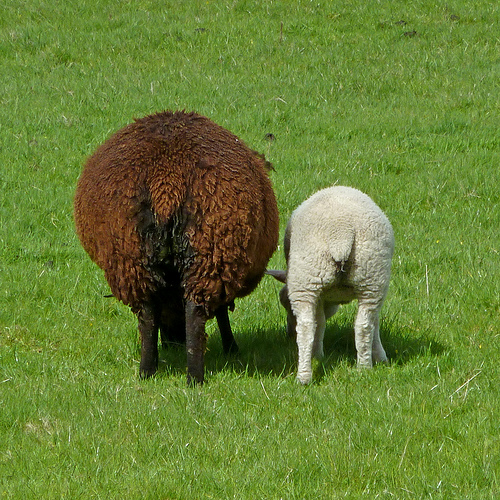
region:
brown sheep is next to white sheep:
[71, 107, 274, 389]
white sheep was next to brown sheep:
[266, 183, 393, 384]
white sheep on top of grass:
[268, 182, 391, 383]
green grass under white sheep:
[0, 2, 498, 497]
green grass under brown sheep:
[4, 1, 498, 497]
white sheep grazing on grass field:
[265, 186, 400, 387]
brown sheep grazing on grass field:
[72, 112, 281, 388]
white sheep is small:
[266, 185, 396, 385]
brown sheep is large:
[71, 108, 281, 388]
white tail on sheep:
[326, 236, 355, 268]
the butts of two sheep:
[77, 102, 422, 386]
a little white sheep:
[271, 170, 433, 395]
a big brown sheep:
[28, 105, 293, 387]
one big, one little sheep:
[38, 89, 435, 402]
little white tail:
[323, 226, 377, 269]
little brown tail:
[134, 140, 207, 225]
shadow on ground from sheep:
[154, 304, 457, 387]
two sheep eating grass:
[56, 73, 496, 424]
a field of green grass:
[0, 0, 499, 494]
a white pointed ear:
[265, 259, 290, 291]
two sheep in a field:
[51, 97, 442, 390]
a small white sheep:
[269, 192, 437, 414]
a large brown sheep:
[33, 87, 300, 404]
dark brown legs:
[90, 293, 235, 398]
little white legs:
[286, 296, 407, 391]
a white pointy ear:
[260, 260, 297, 299]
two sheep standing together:
[52, 92, 437, 425]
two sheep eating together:
[52, 87, 448, 440]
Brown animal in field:
[71, 79, 288, 424]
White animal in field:
[260, 165, 448, 415]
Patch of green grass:
[4, 418, 91, 489]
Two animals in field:
[55, 66, 435, 438]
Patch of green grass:
[138, 437, 185, 494]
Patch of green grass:
[214, 443, 273, 485]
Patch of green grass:
[289, 434, 356, 494]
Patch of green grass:
[376, 429, 443, 493]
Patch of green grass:
[415, 354, 486, 426]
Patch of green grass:
[37, 284, 82, 362]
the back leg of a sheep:
[286, 285, 321, 385]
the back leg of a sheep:
[350, 302, 373, 367]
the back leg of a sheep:
[184, 285, 205, 385]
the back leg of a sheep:
[133, 275, 160, 385]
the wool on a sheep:
[96, 135, 128, 265]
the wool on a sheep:
[293, 208, 324, 272]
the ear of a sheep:
[265, 265, 285, 283]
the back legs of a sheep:
[291, 293, 381, 378]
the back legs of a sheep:
[116, 289, 226, 391]